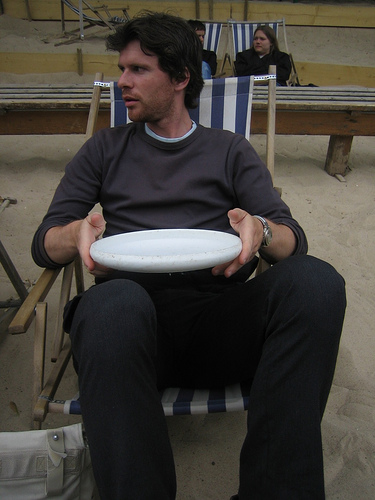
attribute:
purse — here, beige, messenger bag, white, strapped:
[0, 425, 84, 498]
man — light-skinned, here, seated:
[33, 10, 346, 499]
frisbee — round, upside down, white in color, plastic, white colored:
[91, 229, 242, 272]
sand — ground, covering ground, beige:
[1, 20, 373, 499]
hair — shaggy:
[104, 10, 202, 110]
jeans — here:
[202, 60, 210, 78]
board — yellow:
[0, 53, 373, 89]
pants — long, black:
[71, 254, 348, 500]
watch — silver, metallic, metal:
[255, 211, 271, 249]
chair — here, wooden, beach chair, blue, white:
[9, 66, 279, 431]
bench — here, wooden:
[0, 86, 373, 177]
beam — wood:
[0, 111, 374, 136]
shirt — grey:
[141, 123, 198, 144]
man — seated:
[186, 20, 217, 78]